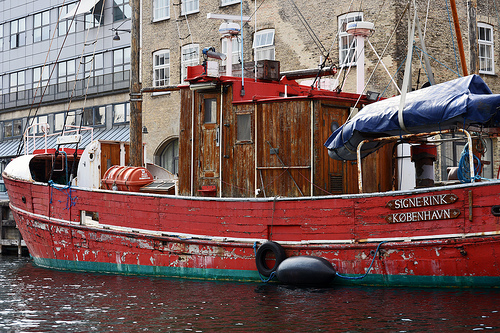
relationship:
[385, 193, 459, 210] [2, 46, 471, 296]
name on boat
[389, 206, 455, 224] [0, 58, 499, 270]
lettering on boat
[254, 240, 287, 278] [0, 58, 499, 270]
black tire on boat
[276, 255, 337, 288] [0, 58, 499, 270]
black object by boat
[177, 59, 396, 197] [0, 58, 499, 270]
cabin on boat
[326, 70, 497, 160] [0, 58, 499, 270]
blue tarp on boat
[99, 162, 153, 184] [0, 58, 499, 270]
barrel on boat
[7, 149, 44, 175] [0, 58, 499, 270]
front of boat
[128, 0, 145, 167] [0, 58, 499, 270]
wooden pole on boat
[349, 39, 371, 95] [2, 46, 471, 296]
pole on boat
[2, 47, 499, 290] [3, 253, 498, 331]
boat docked on river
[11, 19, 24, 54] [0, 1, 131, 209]
window on side of building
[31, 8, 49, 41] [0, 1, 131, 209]
window on side of building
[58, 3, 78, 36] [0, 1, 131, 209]
window on side of building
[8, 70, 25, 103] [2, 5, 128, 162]
window on side of building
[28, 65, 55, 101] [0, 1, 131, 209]
window on side of building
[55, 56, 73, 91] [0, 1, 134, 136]
window on side of building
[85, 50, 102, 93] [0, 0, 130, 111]
window on side of building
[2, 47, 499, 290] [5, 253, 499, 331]
boat in water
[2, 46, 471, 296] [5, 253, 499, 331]
boat in water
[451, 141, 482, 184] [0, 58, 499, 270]
blue hose on boat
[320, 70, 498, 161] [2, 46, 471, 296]
covering on boat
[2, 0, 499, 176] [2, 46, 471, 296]
building behind boat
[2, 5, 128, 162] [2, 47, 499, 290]
building behind boat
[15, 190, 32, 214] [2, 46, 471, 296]
hole in side of boat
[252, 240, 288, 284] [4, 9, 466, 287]
black tire on side of boat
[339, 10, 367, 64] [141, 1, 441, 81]
window on building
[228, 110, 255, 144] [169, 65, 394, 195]
small window in cabin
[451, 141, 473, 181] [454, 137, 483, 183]
blue hose wrapped on a pole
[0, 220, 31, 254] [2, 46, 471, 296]
wooden fence next to boat